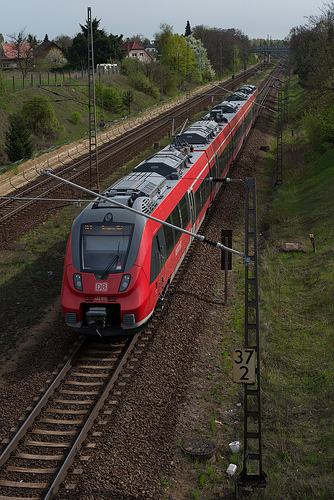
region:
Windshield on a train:
[77, 220, 135, 272]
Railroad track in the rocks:
[27, 349, 139, 493]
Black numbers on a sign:
[233, 350, 255, 379]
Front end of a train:
[57, 172, 187, 341]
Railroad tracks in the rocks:
[5, 139, 151, 203]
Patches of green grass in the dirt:
[184, 216, 241, 492]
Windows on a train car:
[161, 190, 189, 260]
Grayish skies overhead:
[1, 1, 329, 52]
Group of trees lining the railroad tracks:
[139, 27, 248, 95]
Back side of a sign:
[220, 228, 231, 268]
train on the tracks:
[41, 78, 270, 346]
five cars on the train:
[54, 78, 268, 342]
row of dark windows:
[193, 96, 262, 218]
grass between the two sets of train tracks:
[1, 62, 272, 361]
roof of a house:
[3, 37, 39, 56]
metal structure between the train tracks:
[82, 5, 113, 200]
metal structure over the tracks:
[240, 43, 291, 69]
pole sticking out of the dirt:
[221, 239, 233, 307]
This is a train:
[40, 162, 207, 351]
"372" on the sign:
[212, 329, 281, 413]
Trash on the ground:
[213, 427, 246, 486]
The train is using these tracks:
[16, 365, 178, 460]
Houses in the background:
[3, 24, 222, 93]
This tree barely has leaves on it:
[7, 27, 45, 95]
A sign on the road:
[199, 216, 238, 328]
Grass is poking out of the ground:
[218, 290, 311, 401]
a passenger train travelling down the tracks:
[56, 78, 272, 343]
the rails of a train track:
[10, 340, 167, 497]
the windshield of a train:
[80, 218, 130, 276]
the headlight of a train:
[71, 271, 86, 295]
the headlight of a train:
[116, 272, 131, 292]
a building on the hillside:
[2, 36, 72, 77]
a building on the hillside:
[117, 38, 153, 71]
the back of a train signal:
[217, 222, 236, 276]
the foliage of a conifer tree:
[2, 112, 36, 160]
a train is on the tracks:
[43, 77, 262, 343]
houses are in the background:
[2, 25, 189, 81]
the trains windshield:
[78, 219, 142, 277]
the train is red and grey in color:
[144, 87, 254, 296]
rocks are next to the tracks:
[99, 275, 178, 485]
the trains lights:
[64, 265, 138, 292]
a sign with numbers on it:
[216, 343, 262, 394]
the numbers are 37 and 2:
[228, 342, 261, 392]